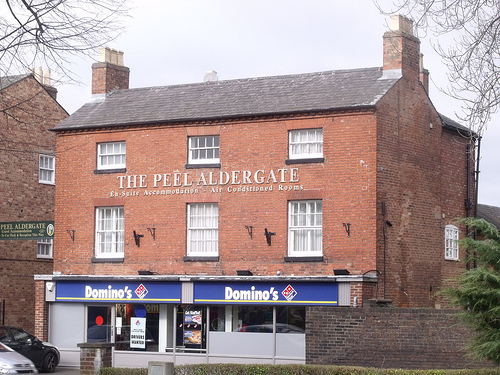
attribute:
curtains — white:
[91, 202, 129, 264]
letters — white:
[105, 167, 313, 195]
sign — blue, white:
[58, 272, 185, 305]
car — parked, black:
[4, 328, 58, 372]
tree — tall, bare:
[411, 4, 499, 305]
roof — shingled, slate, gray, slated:
[60, 77, 377, 119]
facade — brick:
[54, 131, 379, 278]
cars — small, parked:
[3, 323, 59, 374]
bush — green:
[102, 366, 147, 374]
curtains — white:
[95, 141, 125, 171]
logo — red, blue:
[134, 284, 150, 301]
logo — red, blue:
[280, 287, 300, 301]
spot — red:
[92, 315, 106, 325]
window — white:
[185, 133, 223, 167]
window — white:
[285, 124, 326, 167]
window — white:
[183, 200, 222, 262]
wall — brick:
[304, 305, 472, 359]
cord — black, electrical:
[377, 203, 389, 300]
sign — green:
[2, 220, 57, 242]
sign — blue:
[190, 280, 341, 306]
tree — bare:
[3, 1, 109, 86]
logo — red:
[183, 310, 205, 326]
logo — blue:
[130, 308, 148, 318]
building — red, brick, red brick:
[45, 73, 472, 364]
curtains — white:
[442, 224, 462, 262]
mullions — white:
[444, 224, 454, 260]